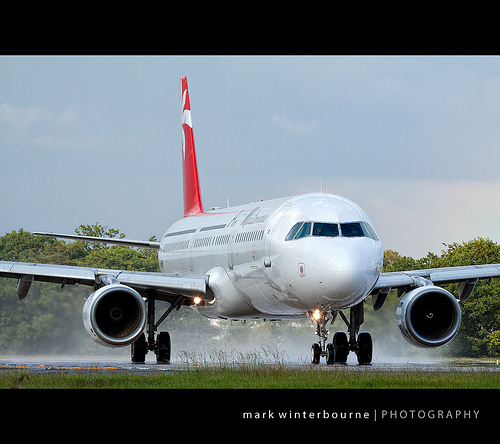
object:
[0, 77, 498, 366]
plane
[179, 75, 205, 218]
tail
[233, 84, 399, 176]
clouds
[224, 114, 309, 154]
clouds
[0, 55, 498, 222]
clouds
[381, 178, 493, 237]
clouds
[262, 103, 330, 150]
clouds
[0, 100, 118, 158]
cloud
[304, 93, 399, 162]
clouds